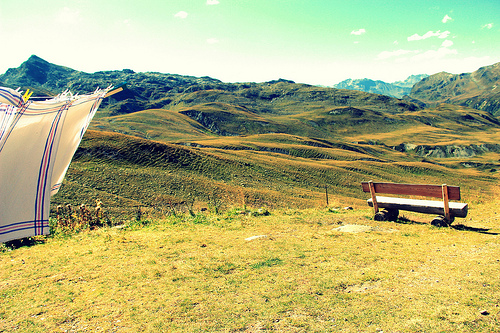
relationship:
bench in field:
[361, 180, 467, 227] [0, 201, 499, 331]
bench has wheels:
[361, 180, 467, 227] [371, 204, 397, 221]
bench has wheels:
[361, 180, 467, 227] [431, 212, 454, 227]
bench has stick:
[361, 180, 467, 227] [369, 181, 379, 217]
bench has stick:
[361, 180, 467, 227] [442, 183, 451, 223]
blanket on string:
[1, 86, 106, 245] [28, 95, 57, 99]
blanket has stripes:
[1, 86, 106, 245] [1, 219, 51, 234]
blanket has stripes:
[1, 86, 106, 245] [1, 89, 24, 107]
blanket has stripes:
[1, 86, 106, 245] [21, 105, 68, 115]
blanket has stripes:
[1, 86, 106, 245] [34, 99, 67, 232]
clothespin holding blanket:
[22, 86, 35, 105] [1, 86, 106, 245]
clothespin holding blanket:
[99, 86, 123, 101] [1, 86, 106, 245]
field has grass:
[0, 201, 499, 331] [0, 209, 498, 331]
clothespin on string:
[22, 86, 35, 105] [28, 95, 57, 99]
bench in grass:
[361, 180, 467, 227] [0, 209, 498, 331]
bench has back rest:
[361, 180, 467, 227] [360, 180, 460, 199]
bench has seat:
[361, 180, 467, 227] [367, 196, 468, 218]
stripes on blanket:
[34, 99, 67, 232] [1, 86, 106, 245]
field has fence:
[0, 201, 499, 331] [53, 201, 199, 231]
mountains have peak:
[2, 53, 499, 111] [24, 55, 49, 70]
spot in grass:
[329, 223, 372, 237] [0, 209, 498, 331]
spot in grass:
[242, 234, 267, 242] [0, 209, 498, 331]